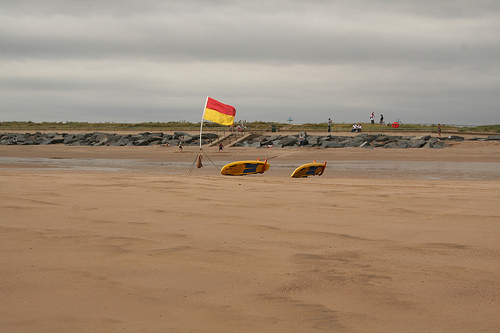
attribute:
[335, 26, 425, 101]
clouds — white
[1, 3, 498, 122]
sky — blue, cloudy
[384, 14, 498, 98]
sky — blue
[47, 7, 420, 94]
clouds — white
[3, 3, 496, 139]
sky — blue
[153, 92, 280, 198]
yellow flag — RED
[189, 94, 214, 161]
flag — white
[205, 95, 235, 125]
flag — yellow, red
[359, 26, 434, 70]
clouds — white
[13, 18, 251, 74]
sky — blue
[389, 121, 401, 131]
kite — red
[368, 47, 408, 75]
clouds — white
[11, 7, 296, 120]
sky — blue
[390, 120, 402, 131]
cloth — red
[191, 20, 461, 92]
sky — cloudy, dark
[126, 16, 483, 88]
clouds — white